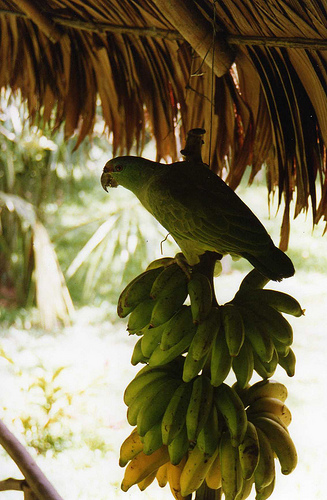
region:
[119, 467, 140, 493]
bottom of a yellow banana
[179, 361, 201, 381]
bottom of a green banana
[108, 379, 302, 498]
bunches of yellow and green bananas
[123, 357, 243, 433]
bunch of green bananas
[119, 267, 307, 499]
large amount of bananas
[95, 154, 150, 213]
head and neck of a tropical bird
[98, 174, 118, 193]
bird beak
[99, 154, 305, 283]
green tropical bird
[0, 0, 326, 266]
bird under a grass hut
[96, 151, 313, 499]
bird perched on bunches of bananas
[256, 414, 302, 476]
A ripe, yellow banana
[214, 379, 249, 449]
An unrippen, green banana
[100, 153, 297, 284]
A green parrot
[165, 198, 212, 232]
Green feathers on a parrot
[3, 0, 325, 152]
The roof of a hut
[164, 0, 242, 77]
A piece of bamboo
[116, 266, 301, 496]
A bunch of green and yellow bananas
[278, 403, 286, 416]
A brown spot on a yellow banana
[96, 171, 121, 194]
The beak of a parrot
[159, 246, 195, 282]
The foot of a parrot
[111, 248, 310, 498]
THESE ARE BANANAS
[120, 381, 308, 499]
THE BANANAS ON THE BOTTOM ARE YELLOW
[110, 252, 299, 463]
THE BANANAS ARE GREEN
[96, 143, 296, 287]
THE MACAW IS GREEN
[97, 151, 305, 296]
THE BIRD IS A MACAW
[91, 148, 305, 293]
THE BIRD IS ON TOP OF THE BANANAS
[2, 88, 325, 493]
THE DAY IS VERY BRIGHT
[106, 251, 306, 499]
THE BANANAS ARE HANGING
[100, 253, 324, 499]
THE BANANAS ARE IN A BUNCH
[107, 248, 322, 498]
THE BUNCH IS VERY LARGE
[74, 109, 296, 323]
a bird on a branch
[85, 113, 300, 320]
a bird on a banana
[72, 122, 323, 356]
a bird on a banana tree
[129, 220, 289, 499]
a bunch of bananas on a branch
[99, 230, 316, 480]
yellow bananas on a branch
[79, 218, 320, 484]
yellow bananas ready to be picked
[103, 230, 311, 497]
yellow bananas that are outside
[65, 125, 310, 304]
bird standing on a tree outside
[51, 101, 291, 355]
a bird is outside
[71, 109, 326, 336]
a green bird outside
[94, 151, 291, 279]
the bird on the big bunch of bananas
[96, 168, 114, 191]
the bird's beak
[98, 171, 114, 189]
the beak on the bird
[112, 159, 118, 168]
the birds eye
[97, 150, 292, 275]
the green bird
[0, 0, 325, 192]
the ceiling made of dried leaves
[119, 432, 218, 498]
a bunch of yellow bananas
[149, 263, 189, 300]
the banana the bird is standing on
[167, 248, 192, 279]
the bird's foot on the banana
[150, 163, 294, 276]
the green feathers on the bird